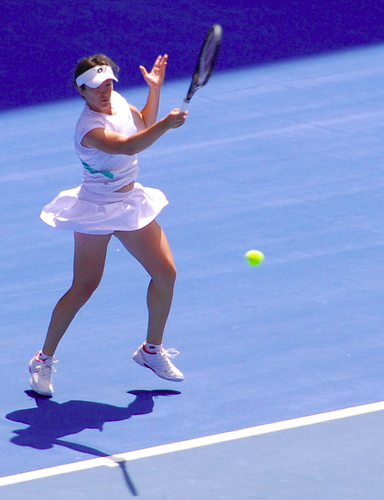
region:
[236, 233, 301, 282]
green tennis ball in the air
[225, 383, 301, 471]
white line on the ground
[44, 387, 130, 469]
shadow on the ground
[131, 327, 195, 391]
foot of the player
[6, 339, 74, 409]
right foot of the player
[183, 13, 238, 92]
racket in person's hand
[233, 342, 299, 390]
blue court on the ground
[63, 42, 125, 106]
hat on the person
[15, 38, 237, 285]
woman playing a game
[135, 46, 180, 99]
hand of the player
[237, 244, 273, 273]
a green tennis ball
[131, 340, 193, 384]
white tennis shoe with laces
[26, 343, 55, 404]
white tennis shoe with laces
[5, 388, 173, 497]
tennis player's shadow on the ground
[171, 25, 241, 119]
black tennis racket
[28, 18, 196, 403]
tennis player swinging her racket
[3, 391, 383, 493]
white line on a tennis court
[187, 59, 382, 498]
blue tennis court with a white line on it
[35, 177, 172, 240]
white flowing tennis skirt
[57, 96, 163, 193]
white tennis top with green stripe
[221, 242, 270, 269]
a yellow color tennis ball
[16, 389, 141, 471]
shadow of the tennis player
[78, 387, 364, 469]
a tennis court market with white color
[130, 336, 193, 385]
a tennis player wearing white colour shoe and socks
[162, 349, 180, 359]
a white color shoe lace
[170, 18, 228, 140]
a woman holding black color tennis bat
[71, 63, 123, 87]
a white color hat in the woman's head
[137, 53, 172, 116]
a woman lifting her hand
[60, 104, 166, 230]
a woman wearing white color dress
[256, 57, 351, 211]
a blue colored tennis court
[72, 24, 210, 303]
a lady playing tennis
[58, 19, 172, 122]
she is holding up her hand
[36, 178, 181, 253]
her skirt is flying up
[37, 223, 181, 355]
she has nice looking legs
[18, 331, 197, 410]
her shoes are white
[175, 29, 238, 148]
she is holding a professional racquet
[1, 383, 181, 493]
her shadow is on the ground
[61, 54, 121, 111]
she is wearing a white visor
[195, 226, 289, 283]
the bad is in the air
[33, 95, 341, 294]
a blue tennis court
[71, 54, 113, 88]
girl has white visor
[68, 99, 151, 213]
girl has white shirt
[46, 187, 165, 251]
girl has white shorts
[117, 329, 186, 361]
white and black socks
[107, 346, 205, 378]
girl has white shoes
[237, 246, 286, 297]
yellow tennis ball in air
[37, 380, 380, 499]
white baseline on court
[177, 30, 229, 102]
girl holds black racket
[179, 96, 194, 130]
white grip on racket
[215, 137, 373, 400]
blue hard court around woman